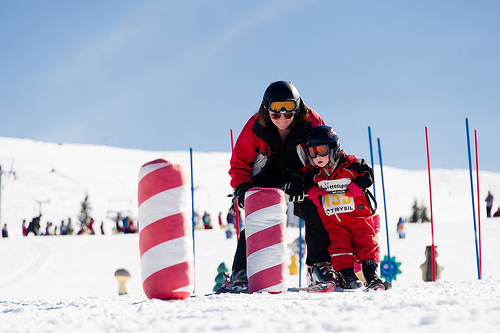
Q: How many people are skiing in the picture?
A: 2.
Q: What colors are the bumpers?
A: Red and white.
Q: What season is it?
A: Winter.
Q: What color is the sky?
A: Blue.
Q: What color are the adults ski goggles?
A: Yellow.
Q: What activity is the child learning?
A: Skiing.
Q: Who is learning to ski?
A: A child.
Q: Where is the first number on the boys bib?
A: 1.